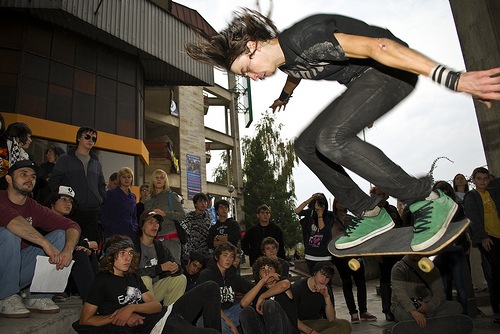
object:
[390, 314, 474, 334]
skateboard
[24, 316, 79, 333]
ground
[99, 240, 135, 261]
band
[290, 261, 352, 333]
boy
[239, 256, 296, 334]
boy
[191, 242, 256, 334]
boy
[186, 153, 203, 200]
poster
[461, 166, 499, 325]
kid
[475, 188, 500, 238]
shirt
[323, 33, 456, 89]
arm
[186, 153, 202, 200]
advertisement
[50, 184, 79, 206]
hat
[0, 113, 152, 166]
accent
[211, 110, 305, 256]
tree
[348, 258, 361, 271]
wheels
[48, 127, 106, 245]
boy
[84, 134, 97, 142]
glasses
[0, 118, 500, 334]
crowd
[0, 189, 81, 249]
shirt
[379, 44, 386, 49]
scab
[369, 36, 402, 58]
elbow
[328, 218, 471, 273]
skate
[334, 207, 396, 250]
green shoe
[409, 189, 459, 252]
green shoe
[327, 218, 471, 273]
board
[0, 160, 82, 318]
man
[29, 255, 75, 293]
paper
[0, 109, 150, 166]
orange trim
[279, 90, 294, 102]
wrist bands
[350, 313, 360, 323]
shoes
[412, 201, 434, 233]
laces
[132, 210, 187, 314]
man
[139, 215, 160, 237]
person's head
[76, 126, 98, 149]
person's head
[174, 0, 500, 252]
man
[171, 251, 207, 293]
boys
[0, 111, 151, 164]
bar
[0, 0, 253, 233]
building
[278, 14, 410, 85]
shirt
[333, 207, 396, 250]
feet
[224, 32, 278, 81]
head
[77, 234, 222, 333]
person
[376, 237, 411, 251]
grip tape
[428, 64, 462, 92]
bracelets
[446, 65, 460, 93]
wrist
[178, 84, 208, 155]
wall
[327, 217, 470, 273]
skateboard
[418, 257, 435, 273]
wheel